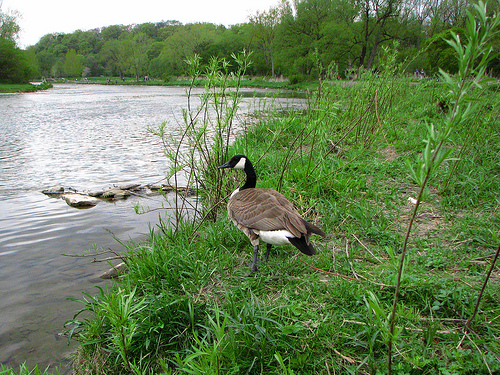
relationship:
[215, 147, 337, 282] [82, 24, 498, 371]
goose walking in grass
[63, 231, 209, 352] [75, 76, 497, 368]
grass growing on bank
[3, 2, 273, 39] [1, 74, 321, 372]
sky reflected in water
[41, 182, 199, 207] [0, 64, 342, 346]
rocks on surface of water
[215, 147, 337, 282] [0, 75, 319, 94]
goose on river bank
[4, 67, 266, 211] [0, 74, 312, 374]
water in river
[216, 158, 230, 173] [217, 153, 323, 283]
bill on goose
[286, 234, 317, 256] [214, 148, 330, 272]
feathers on goose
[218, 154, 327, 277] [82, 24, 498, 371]
goose standing in grass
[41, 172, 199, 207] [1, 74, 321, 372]
rocks in water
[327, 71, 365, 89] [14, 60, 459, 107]
land on river bank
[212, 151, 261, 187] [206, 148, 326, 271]
head on bird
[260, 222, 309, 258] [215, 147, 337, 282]
feathers on goose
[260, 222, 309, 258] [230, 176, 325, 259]
feathers under wing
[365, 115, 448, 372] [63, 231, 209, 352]
stick in grass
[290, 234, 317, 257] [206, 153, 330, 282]
feathers on duck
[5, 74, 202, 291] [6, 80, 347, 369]
river around bend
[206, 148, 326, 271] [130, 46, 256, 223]
bird behind green plant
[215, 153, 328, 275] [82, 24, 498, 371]
duck walking in grass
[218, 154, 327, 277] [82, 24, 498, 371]
goose in grass